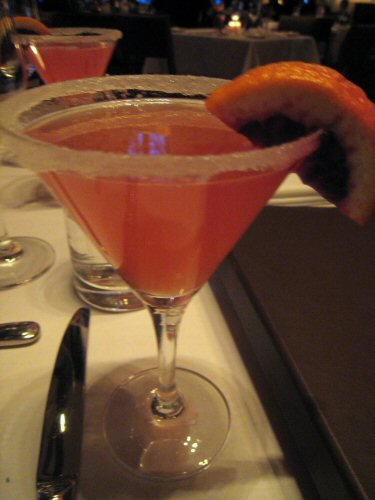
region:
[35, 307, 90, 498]
A knife on the table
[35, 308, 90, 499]
The knife is silver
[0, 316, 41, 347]
Silverware next to the knife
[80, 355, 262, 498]
A shadow on the table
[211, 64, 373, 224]
A slice of fruit on the glass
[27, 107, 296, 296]
A pink beverage in the glass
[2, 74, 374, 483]
A glass on the table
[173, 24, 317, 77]
A table across the room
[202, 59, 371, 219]
a slice of blood orange on the glass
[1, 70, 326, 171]
the salt on the rim of the glass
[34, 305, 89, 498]
the knife sitting on the table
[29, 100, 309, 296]
the drink in the glass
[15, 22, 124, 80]
another drink on the table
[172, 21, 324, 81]
another table in the restaurant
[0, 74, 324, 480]
a margarita glass on the table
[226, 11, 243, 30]
the lights on the table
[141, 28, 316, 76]
the tablecloth on the table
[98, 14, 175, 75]
the chair by the table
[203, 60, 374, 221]
sliced fruit on the side of the glass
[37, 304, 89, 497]
a silver knife on the table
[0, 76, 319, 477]
a martini glass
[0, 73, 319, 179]
rim of the glass has sugar on it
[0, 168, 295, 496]
a white table cloth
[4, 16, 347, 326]
the two martinis are full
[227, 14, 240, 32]
a candle on the table is burning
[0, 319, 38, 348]
handle of silverware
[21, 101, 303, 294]
a pink cocktail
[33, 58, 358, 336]
a margarita in a cup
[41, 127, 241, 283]
salt on the rim of a glass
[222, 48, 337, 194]
a fruit ont he glass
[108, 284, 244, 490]
a table with a glass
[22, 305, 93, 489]
silverware on the table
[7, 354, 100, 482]
a knife on the table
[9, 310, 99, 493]
a table with silverware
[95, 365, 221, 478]
bottom of the glass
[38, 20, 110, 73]
martini in the glass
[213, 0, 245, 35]
candle in the background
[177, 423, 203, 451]
reflection on the glass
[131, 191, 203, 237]
martini in the glass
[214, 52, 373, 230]
fruit hanging on glass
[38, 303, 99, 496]
butter knife on table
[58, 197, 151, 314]
empty glass on table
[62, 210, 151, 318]
glass ont able is empty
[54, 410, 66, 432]
reflection of light in knife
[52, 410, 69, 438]
light reflection in knife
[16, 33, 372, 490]
martini glass on the table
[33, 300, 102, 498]
knife next to glass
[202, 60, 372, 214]
wedge on the rim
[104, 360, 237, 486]
base of the glass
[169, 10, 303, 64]
table in in the background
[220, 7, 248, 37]
candle on the table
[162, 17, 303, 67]
white table cloth on table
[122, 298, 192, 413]
stem of the glass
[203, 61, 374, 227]
fruit attached to glass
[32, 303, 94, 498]
knife to left of glass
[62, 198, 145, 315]
glass before glass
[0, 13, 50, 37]
fruit in glass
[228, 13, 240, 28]
candle on table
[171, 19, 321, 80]
tablecloth covers table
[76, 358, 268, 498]
shadow cast by glass